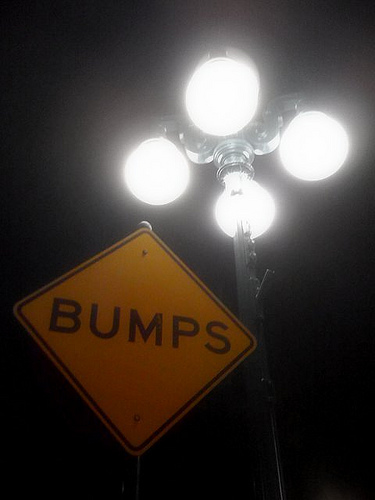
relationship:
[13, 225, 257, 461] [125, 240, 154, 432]
sign fastened by bolts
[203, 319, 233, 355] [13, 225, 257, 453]
s on sign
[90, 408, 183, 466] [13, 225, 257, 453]
bottom of sign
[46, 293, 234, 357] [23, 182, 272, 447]
word on a sign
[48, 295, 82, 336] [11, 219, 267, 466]
letter on a sign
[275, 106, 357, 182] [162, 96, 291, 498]
light on lamp post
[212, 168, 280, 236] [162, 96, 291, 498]
light on lamp post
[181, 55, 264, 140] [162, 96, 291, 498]
light on lamp post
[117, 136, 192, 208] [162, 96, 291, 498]
light on lamp post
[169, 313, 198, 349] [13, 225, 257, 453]
letter on sign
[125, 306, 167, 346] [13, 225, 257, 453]
letter on sign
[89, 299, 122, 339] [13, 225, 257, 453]
letter on sign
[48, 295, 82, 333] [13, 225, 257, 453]
letter on sign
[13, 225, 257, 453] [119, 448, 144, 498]
sign on pole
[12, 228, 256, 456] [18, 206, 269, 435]
boarder on sign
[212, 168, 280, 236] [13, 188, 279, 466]
light above sign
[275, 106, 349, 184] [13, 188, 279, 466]
light above sign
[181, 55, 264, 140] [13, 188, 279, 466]
light above sign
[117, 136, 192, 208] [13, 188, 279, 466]
light above sign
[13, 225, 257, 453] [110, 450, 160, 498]
sign on a pole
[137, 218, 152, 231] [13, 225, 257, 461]
top on sign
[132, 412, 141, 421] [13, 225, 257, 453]
bolt on sign